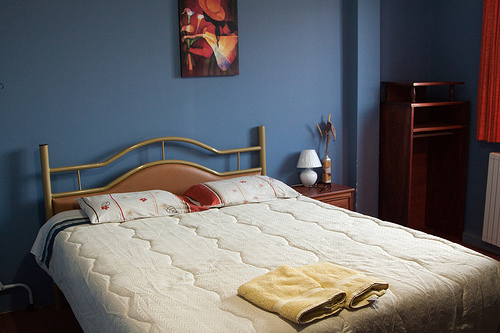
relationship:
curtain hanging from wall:
[474, 4, 499, 145] [435, 1, 499, 249]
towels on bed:
[234, 256, 391, 332] [34, 122, 483, 327]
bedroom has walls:
[1, 4, 498, 329] [3, 2, 495, 167]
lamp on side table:
[296, 149, 322, 187] [285, 179, 358, 213]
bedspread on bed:
[272, 202, 349, 248] [34, 122, 483, 327]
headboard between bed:
[28, 121, 274, 205] [31, 166, 481, 331]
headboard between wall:
[28, 121, 274, 205] [0, 2, 391, 278]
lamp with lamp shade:
[298, 169, 318, 182] [293, 148, 324, 169]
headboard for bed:
[38, 125, 266, 218] [34, 122, 483, 327]